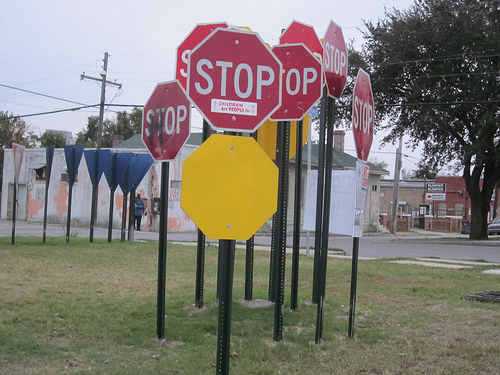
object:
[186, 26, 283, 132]
stop sign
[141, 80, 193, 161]
stop sign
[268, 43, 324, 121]
stop sign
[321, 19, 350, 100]
stop sign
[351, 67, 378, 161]
stop sign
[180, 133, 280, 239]
sign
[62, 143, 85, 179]
sign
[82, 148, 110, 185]
sign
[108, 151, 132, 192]
sign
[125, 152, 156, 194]
sign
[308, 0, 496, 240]
tree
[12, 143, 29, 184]
sign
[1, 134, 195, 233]
building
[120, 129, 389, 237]
building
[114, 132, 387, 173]
roof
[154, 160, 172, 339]
post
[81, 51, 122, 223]
power pole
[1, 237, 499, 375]
grass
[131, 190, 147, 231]
person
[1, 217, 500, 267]
street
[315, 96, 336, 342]
pole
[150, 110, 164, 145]
tagging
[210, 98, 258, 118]
sticker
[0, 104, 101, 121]
electrical line